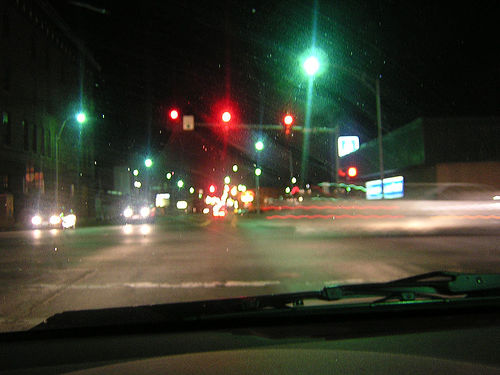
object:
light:
[297, 49, 326, 79]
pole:
[370, 63, 387, 199]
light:
[70, 110, 92, 128]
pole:
[54, 114, 73, 228]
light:
[211, 100, 242, 131]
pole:
[298, 79, 312, 191]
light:
[167, 108, 180, 121]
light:
[141, 207, 152, 217]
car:
[119, 198, 156, 222]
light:
[50, 215, 60, 225]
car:
[32, 206, 63, 227]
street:
[0, 212, 499, 332]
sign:
[183, 116, 195, 131]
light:
[283, 114, 295, 126]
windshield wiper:
[29, 269, 500, 330]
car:
[1, 269, 498, 374]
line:
[18, 280, 369, 288]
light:
[255, 140, 265, 151]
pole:
[286, 127, 294, 202]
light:
[255, 167, 262, 176]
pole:
[254, 148, 259, 217]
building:
[338, 116, 499, 196]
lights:
[206, 184, 219, 196]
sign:
[364, 175, 405, 199]